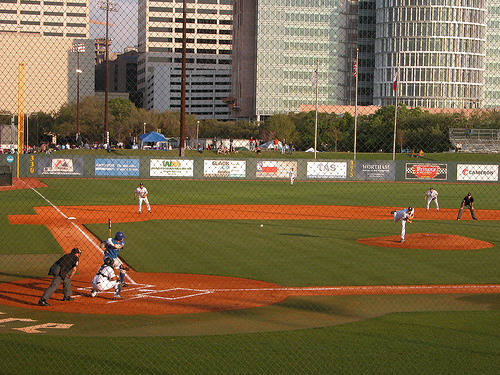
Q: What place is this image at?
A: It is at the field.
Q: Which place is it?
A: It is a field.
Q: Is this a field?
A: Yes, it is a field.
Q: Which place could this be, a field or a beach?
A: It is a field.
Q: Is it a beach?
A: No, it is a field.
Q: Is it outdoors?
A: Yes, it is outdoors.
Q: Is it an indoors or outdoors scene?
A: It is outdoors.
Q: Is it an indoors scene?
A: No, it is outdoors.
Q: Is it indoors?
A: No, it is outdoors.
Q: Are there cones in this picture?
A: No, there are no cones.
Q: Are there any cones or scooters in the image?
A: No, there are no cones or scooters.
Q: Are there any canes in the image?
A: No, there are no canes.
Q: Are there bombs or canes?
A: No, there are no canes or bombs.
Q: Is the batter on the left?
A: Yes, the batter is on the left of the image.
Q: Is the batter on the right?
A: No, the batter is on the left of the image.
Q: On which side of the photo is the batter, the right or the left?
A: The batter is on the left of the image.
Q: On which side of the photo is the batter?
A: The batter is on the left of the image.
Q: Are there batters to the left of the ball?
A: Yes, there is a batter to the left of the ball.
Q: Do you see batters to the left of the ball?
A: Yes, there is a batter to the left of the ball.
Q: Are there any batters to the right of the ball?
A: No, the batter is to the left of the ball.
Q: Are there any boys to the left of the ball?
A: No, there is a batter to the left of the ball.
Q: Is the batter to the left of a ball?
A: Yes, the batter is to the left of a ball.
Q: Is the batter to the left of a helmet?
A: No, the batter is to the left of a ball.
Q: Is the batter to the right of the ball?
A: No, the batter is to the left of the ball.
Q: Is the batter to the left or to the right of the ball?
A: The batter is to the left of the ball.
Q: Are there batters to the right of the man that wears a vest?
A: Yes, there is a batter to the right of the man.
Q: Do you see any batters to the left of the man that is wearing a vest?
A: No, the batter is to the right of the man.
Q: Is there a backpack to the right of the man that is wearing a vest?
A: No, there is a batter to the right of the man.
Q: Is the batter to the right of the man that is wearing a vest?
A: Yes, the batter is to the right of the man.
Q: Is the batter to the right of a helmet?
A: No, the batter is to the right of the man.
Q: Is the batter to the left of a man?
A: No, the batter is to the right of a man.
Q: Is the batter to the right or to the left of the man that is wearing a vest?
A: The batter is to the right of the man.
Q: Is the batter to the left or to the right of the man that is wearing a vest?
A: The batter is to the right of the man.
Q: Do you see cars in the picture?
A: No, there are no cars.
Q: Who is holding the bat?
A: The man is holding the bat.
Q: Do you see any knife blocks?
A: No, there are no knife blocks.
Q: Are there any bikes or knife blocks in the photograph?
A: No, there are no knife blocks or bikes.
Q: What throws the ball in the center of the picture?
A: The pitcher throws the ball.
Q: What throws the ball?
A: The pitcher throws the ball.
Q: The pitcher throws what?
A: The pitcher throws the ball.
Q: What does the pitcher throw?
A: The pitcher throws the ball.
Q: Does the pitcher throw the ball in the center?
A: Yes, the pitcher throws the ball.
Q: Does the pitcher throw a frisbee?
A: No, the pitcher throws the ball.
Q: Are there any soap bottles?
A: No, there are no soap bottles.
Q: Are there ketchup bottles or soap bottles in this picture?
A: No, there are no soap bottles or ketchup bottles.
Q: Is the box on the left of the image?
A: Yes, the box is on the left of the image.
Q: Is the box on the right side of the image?
A: No, the box is on the left of the image.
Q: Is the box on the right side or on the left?
A: The box is on the left of the image.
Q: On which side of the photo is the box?
A: The box is on the left of the image.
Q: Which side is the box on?
A: The box is on the left of the image.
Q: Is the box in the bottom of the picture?
A: Yes, the box is in the bottom of the image.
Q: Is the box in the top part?
A: No, the box is in the bottom of the image.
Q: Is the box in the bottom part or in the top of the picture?
A: The box is in the bottom of the image.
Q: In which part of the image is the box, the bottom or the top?
A: The box is in the bottom of the image.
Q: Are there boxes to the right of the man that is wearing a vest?
A: Yes, there is a box to the right of the man.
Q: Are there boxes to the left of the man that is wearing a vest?
A: No, the box is to the right of the man.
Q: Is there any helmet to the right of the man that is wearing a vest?
A: No, there is a box to the right of the man.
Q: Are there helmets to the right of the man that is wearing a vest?
A: No, there is a box to the right of the man.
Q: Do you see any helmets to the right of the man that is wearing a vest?
A: No, there is a box to the right of the man.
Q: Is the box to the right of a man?
A: Yes, the box is to the right of a man.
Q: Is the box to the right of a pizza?
A: No, the box is to the right of a man.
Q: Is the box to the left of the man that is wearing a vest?
A: No, the box is to the right of the man.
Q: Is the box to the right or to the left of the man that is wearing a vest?
A: The box is to the right of the man.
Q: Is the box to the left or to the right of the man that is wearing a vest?
A: The box is to the right of the man.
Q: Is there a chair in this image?
A: No, there are no chairs.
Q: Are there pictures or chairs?
A: No, there are no chairs or pictures.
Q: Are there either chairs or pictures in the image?
A: No, there are no chairs or pictures.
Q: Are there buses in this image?
A: No, there are no buses.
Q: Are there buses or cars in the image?
A: No, there are no buses or cars.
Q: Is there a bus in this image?
A: No, there are no buses.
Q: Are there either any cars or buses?
A: No, there are no buses or cars.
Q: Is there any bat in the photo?
A: Yes, there is a bat.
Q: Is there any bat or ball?
A: Yes, there is a bat.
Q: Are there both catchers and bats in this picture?
A: Yes, there are both a bat and a catcher.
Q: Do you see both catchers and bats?
A: Yes, there are both a bat and a catcher.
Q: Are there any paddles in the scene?
A: No, there are no paddles.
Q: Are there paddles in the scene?
A: No, there are no paddles.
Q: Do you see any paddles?
A: No, there are no paddles.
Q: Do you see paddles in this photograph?
A: No, there are no paddles.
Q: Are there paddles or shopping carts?
A: No, there are no paddles or shopping carts.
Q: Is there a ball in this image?
A: Yes, there is a ball.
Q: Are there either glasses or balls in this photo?
A: Yes, there is a ball.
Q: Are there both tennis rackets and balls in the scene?
A: No, there is a ball but no rackets.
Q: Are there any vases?
A: No, there are no vases.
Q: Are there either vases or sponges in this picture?
A: No, there are no vases or sponges.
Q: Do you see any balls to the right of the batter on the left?
A: Yes, there is a ball to the right of the batter.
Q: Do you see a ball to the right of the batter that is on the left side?
A: Yes, there is a ball to the right of the batter.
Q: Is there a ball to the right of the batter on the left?
A: Yes, there is a ball to the right of the batter.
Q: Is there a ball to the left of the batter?
A: No, the ball is to the right of the batter.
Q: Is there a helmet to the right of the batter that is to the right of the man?
A: No, there is a ball to the right of the batter.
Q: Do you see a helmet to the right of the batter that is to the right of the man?
A: No, there is a ball to the right of the batter.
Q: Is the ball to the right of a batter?
A: Yes, the ball is to the right of a batter.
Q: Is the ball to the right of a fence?
A: No, the ball is to the right of a batter.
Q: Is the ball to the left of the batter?
A: No, the ball is to the right of the batter.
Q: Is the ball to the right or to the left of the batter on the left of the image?
A: The ball is to the right of the batter.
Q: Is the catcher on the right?
A: No, the catcher is on the left of the image.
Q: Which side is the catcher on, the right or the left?
A: The catcher is on the left of the image.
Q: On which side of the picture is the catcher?
A: The catcher is on the left of the image.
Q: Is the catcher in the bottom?
A: Yes, the catcher is in the bottom of the image.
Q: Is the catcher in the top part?
A: No, the catcher is in the bottom of the image.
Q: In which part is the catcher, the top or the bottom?
A: The catcher is in the bottom of the image.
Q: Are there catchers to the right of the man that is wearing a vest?
A: Yes, there is a catcher to the right of the man.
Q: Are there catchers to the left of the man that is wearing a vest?
A: No, the catcher is to the right of the man.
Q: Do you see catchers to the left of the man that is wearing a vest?
A: No, the catcher is to the right of the man.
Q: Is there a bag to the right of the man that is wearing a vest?
A: No, there is a catcher to the right of the man.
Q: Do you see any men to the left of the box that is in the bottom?
A: Yes, there is a man to the left of the box.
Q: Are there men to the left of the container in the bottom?
A: Yes, there is a man to the left of the box.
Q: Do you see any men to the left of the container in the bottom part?
A: Yes, there is a man to the left of the box.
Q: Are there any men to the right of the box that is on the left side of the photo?
A: No, the man is to the left of the box.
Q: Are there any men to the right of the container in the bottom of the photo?
A: No, the man is to the left of the box.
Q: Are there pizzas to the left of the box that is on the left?
A: No, there is a man to the left of the box.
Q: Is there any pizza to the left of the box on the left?
A: No, there is a man to the left of the box.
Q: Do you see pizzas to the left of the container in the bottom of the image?
A: No, there is a man to the left of the box.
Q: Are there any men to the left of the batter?
A: Yes, there is a man to the left of the batter.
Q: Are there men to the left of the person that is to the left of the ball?
A: Yes, there is a man to the left of the batter.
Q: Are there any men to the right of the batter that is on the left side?
A: No, the man is to the left of the batter.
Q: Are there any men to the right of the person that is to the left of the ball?
A: No, the man is to the left of the batter.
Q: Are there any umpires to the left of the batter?
A: No, there is a man to the left of the batter.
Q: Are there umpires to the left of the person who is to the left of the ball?
A: No, there is a man to the left of the batter.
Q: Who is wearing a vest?
A: The man is wearing a vest.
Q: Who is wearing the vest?
A: The man is wearing a vest.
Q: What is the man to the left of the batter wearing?
A: The man is wearing a vest.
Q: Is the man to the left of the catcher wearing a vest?
A: Yes, the man is wearing a vest.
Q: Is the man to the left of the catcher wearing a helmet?
A: No, the man is wearing a vest.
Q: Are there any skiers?
A: No, there are no skiers.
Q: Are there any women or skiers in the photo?
A: No, there are no skiers or women.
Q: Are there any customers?
A: No, there are no customers.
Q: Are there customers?
A: No, there are no customers.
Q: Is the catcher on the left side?
A: Yes, the catcher is on the left of the image.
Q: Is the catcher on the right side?
A: No, the catcher is on the left of the image.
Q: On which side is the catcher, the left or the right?
A: The catcher is on the left of the image.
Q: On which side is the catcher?
A: The catcher is on the left of the image.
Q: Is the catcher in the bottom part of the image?
A: Yes, the catcher is in the bottom of the image.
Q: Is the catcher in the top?
A: No, the catcher is in the bottom of the image.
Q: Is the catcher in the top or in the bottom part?
A: The catcher is in the bottom of the image.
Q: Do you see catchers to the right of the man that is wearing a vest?
A: Yes, there is a catcher to the right of the man.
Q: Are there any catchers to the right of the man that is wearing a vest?
A: Yes, there is a catcher to the right of the man.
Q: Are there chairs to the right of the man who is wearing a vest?
A: No, there is a catcher to the right of the man.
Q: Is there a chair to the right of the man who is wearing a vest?
A: No, there is a catcher to the right of the man.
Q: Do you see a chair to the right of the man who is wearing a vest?
A: No, there is a catcher to the right of the man.